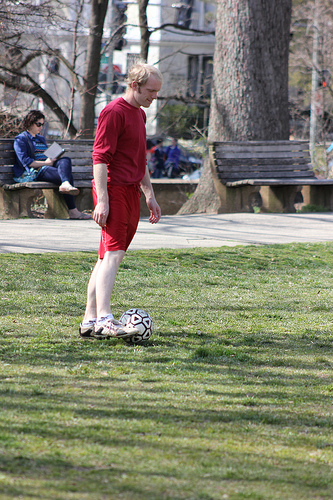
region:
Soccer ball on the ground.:
[104, 302, 168, 343]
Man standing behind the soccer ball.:
[60, 52, 169, 356]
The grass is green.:
[82, 408, 220, 463]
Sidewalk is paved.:
[161, 207, 300, 232]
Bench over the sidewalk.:
[201, 131, 329, 185]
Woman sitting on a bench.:
[11, 110, 75, 210]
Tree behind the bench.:
[209, 8, 295, 142]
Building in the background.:
[140, 17, 223, 108]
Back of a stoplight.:
[105, 3, 135, 51]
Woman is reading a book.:
[27, 133, 73, 161]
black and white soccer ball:
[114, 305, 155, 341]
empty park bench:
[200, 134, 332, 213]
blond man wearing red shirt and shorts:
[81, 48, 168, 351]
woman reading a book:
[6, 105, 92, 223]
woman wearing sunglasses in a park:
[15, 106, 92, 222]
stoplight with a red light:
[311, 66, 330, 89]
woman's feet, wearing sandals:
[55, 177, 94, 221]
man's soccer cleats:
[66, 308, 136, 344]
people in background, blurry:
[143, 133, 195, 182]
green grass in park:
[95, 394, 202, 465]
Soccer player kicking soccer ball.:
[66, 54, 190, 348]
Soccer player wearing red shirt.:
[77, 58, 170, 346]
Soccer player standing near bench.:
[11, 56, 206, 358]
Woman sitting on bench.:
[8, 79, 84, 219]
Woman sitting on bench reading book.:
[8, 88, 87, 220]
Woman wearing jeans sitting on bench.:
[10, 91, 85, 208]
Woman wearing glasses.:
[11, 101, 78, 207]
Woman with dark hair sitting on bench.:
[13, 101, 81, 215]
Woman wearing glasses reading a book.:
[11, 98, 83, 223]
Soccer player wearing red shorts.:
[79, 59, 168, 355]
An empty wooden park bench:
[210, 136, 331, 189]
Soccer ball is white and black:
[117, 304, 154, 343]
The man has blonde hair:
[125, 61, 164, 109]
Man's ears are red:
[129, 79, 139, 89]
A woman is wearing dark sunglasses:
[18, 107, 52, 136]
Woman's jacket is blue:
[12, 107, 49, 171]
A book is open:
[43, 141, 67, 162]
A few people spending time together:
[147, 133, 189, 175]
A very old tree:
[208, 26, 293, 91]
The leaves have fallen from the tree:
[4, 0, 86, 40]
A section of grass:
[36, 412, 156, 480]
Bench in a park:
[208, 136, 329, 208]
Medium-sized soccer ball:
[118, 303, 149, 336]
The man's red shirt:
[106, 106, 143, 180]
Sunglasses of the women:
[32, 119, 41, 122]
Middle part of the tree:
[74, 0, 103, 132]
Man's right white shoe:
[92, 313, 132, 333]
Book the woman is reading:
[44, 138, 61, 159]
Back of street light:
[111, 3, 129, 48]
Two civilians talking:
[153, 136, 182, 178]